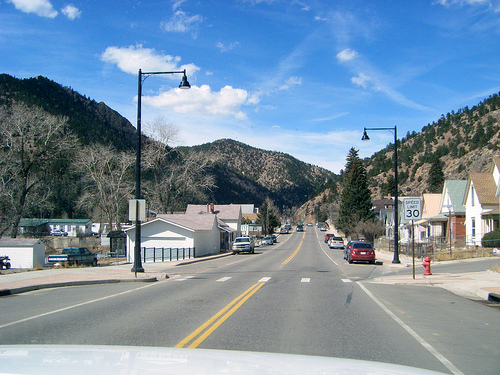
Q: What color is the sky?
A: Blue.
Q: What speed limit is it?
A: 30.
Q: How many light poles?
A: 2.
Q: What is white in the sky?
A: Clouds.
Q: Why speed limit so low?
A: Residential area.